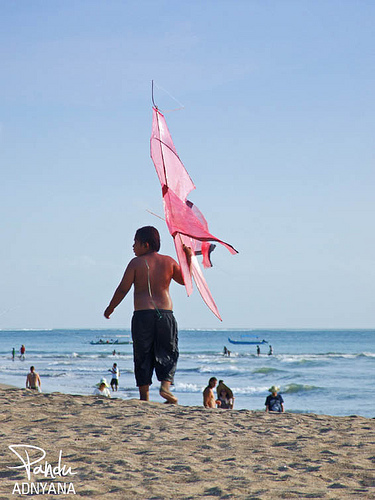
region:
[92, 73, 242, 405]
a boy holding a kite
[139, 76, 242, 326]
a kite color pink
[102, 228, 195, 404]
boy wears black pants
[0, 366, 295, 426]
people in the beach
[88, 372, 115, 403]
woman wears a green hat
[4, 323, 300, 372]
people in the ocean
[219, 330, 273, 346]
a blue boat in the ocean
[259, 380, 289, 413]
woman wearing a blue shirt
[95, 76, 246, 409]
boy holding a pink kite on right hand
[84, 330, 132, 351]
a boat in the ocean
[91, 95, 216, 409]
boy holding a kite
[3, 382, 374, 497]
sand on a beach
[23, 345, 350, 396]
wave after wave near shor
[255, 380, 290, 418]
a person with a hat with a brim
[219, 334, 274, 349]
a boat on the water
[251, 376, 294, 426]
a person wearing a shirt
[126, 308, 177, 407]
long pants on the boy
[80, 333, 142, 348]
a boat with multiple people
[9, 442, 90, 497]
logo of the photographer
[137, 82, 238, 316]
a kite of two shades of pink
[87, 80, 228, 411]
Boy carrying a kite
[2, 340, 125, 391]
People enjoying the ocean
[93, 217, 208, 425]
Boy walking in the sand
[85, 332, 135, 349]
People in a boat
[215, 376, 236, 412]
Lady in a sun hat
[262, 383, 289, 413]
Man in a sun hat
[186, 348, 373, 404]
Light waves in the ocean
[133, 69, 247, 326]
Large pink kite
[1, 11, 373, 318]
Foggy grey sky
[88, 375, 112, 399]
Lady in white sun hat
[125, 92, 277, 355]
a red, ruffly kite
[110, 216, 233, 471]
fat kid on the beach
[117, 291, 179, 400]
fat kid wearing long blue shorts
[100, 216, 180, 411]
fat kid is holding the kite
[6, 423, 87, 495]
watermark says Pandu ADNYANA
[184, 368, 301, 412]
beachgoers in the background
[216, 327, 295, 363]
boat on the water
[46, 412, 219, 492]
footprints in the sand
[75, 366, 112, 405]
woman wearing a floppy hat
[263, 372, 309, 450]
man wearing a large hat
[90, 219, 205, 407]
person on the beach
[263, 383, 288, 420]
person on the beach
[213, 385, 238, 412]
person on the beach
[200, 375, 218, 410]
person on the beach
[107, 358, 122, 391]
person on the beach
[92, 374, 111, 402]
person on the beach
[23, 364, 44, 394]
person on the beach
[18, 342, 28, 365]
person on the beach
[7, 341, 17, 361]
person on the beach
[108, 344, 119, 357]
person on the beach